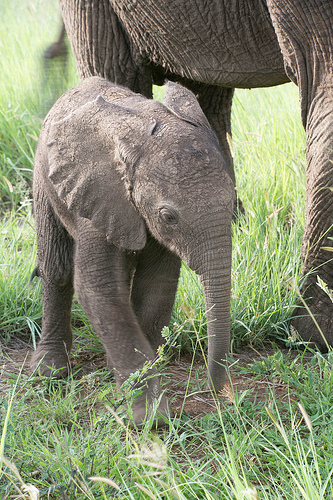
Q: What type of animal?
A: Elephant.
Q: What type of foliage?
A: Grass.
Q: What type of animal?
A: Elephant.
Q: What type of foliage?
A: Grass.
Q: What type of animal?
A: Elephant.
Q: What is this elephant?
A: The bigger elephant.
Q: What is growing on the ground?
A: Long green grass.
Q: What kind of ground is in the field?
A: Sparse.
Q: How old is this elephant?
A: Young.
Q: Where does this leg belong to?
A: To that of a adult elephant.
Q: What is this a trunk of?
A: A young elephant.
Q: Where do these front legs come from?
A: From the young elephant.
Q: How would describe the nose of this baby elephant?
A: It is long.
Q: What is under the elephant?
A: Green grass.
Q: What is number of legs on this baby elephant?
A: Four legs.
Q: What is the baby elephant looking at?
A: The camera.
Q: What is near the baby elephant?
A: The mother.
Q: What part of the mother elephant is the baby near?
A: The legs.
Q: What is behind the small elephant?
A: The large mother elephant.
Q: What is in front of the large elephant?
A: A baby elephant.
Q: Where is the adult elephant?
A: Behind the baby.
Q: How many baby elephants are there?
A: One.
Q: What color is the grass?
A: Green.